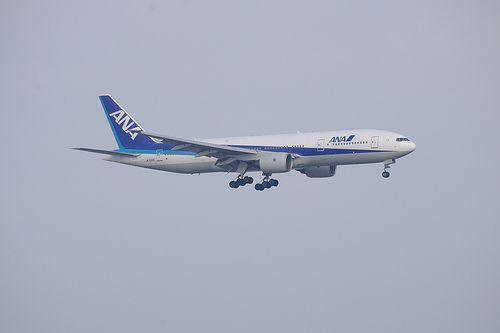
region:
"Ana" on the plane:
[78, 83, 166, 173]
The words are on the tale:
[87, 76, 178, 186]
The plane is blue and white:
[71, 70, 428, 217]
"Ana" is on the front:
[288, 120, 353, 152]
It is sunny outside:
[21, 9, 462, 281]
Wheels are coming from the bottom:
[211, 167, 305, 218]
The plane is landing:
[67, 72, 494, 326]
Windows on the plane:
[388, 122, 416, 147]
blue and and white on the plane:
[71, 76, 418, 197]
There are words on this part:
[134, 146, 182, 174]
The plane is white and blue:
[82, 86, 419, 202]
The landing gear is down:
[218, 146, 410, 190]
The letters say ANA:
[92, 93, 159, 175]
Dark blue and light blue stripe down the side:
[96, 96, 396, 169]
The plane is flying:
[62, 86, 417, 230]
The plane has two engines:
[257, 143, 344, 183]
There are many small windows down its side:
[256, 137, 368, 147]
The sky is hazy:
[74, 201, 306, 313]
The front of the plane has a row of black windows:
[388, 129, 413, 148]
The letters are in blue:
[326, 134, 369, 148]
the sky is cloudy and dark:
[379, 219, 400, 276]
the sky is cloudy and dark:
[333, 255, 347, 282]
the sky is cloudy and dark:
[337, 254, 352, 285]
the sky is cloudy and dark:
[299, 217, 313, 253]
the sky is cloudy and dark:
[314, 251, 326, 273]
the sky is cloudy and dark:
[297, 227, 310, 262]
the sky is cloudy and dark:
[292, 251, 302, 273]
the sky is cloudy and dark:
[301, 291, 313, 309]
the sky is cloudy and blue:
[290, 230, 315, 279]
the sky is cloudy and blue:
[324, 249, 336, 272]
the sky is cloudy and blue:
[344, 253, 364, 285]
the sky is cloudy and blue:
[290, 288, 298, 305]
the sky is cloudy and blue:
[301, 245, 312, 267]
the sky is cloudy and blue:
[329, 243, 346, 273]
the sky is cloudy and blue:
[324, 294, 341, 319]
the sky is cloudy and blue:
[330, 275, 342, 299]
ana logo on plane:
[111, 110, 149, 147]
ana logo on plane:
[320, 124, 347, 141]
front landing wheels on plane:
[373, 168, 398, 182]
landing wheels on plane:
[251, 178, 286, 190]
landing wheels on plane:
[224, 170, 248, 192]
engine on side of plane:
[308, 165, 335, 179]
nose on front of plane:
[386, 135, 420, 160]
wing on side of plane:
[137, 117, 236, 163]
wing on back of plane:
[79, 142, 129, 159]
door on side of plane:
[368, 131, 378, 151]